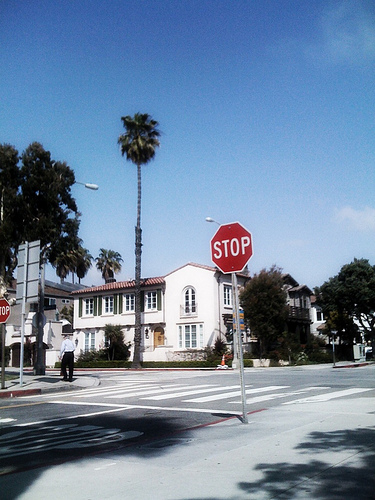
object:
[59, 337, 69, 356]
sleeves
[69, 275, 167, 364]
house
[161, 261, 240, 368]
house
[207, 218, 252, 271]
sign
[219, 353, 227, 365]
traffic cone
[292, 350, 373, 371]
sidewalk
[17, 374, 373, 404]
crossing walk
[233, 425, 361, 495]
shadow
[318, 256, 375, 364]
trees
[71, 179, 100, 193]
street light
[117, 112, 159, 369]
palm tree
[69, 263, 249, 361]
building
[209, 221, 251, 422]
stop sign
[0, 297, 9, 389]
stop sign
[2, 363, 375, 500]
street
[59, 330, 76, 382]
man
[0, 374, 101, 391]
sidewalk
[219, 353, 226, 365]
orange cone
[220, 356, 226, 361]
white strpe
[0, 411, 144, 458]
stop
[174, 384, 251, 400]
white line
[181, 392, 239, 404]
white line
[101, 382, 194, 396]
white line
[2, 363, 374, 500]
road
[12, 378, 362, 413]
street crossing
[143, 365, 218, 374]
curve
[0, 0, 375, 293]
sky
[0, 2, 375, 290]
cloud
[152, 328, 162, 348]
door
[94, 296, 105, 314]
shutter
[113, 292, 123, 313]
shutter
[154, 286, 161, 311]
shutter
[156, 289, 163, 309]
shutter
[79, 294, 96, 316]
window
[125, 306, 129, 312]
window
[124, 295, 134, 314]
window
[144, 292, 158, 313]
window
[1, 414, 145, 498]
pavement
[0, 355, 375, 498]
grey pavement